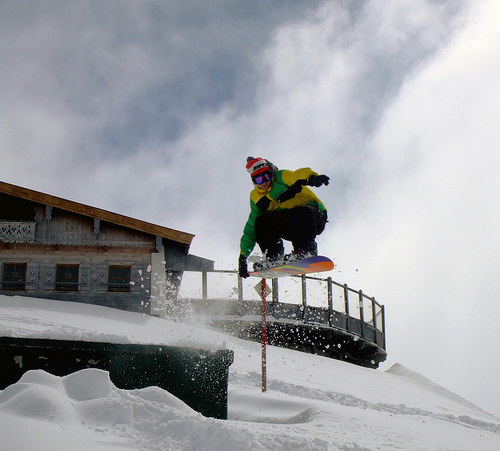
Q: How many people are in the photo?
A: One.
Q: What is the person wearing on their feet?
A: Skis.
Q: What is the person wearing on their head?
A: Hat.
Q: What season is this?
A: Winter.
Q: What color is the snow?
A: White.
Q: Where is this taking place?
A: A ski slope.